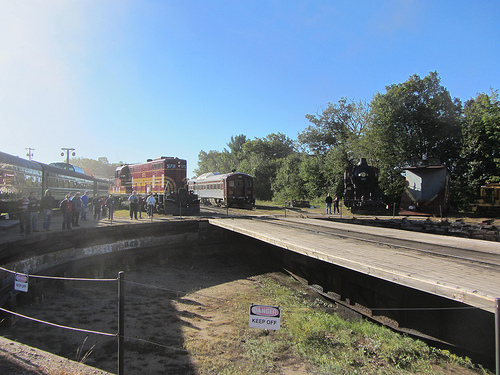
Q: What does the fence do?
A: Keep people away.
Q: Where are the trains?
A: At the station.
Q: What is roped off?
A: A special area.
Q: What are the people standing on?
A: Platform.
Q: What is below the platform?
A: Dirt.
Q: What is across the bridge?
A: Train tracks.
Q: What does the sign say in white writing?
A: Danger.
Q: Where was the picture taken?
A: Train station.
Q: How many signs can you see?
A: 2.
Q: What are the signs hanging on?
A: Chain.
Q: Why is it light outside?
A: Sun.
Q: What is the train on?
A: Tracks.